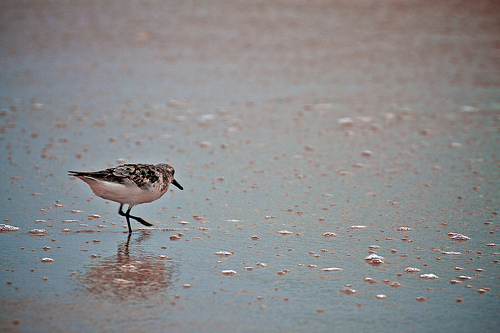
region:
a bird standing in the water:
[66, 146, 195, 229]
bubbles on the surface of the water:
[247, 204, 465, 313]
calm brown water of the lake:
[245, 30, 456, 97]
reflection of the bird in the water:
[84, 245, 179, 305]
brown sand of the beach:
[13, 288, 176, 331]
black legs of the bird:
[101, 206, 159, 239]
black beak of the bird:
[169, 177, 189, 192]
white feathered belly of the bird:
[85, 183, 166, 211]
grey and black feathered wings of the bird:
[85, 162, 165, 189]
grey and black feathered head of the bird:
[157, 158, 178, 183]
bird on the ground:
[75, 130, 207, 244]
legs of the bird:
[113, 207, 158, 245]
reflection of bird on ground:
[111, 245, 177, 305]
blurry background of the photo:
[257, 24, 337, 81]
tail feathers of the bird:
[52, 151, 102, 205]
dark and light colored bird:
[76, 149, 198, 234]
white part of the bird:
[94, 185, 154, 212]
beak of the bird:
[171, 173, 192, 197]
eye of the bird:
[167, 165, 176, 181]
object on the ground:
[206, 235, 239, 268]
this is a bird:
[67, 160, 199, 227]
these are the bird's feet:
[110, 202, 160, 234]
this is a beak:
[168, 177, 185, 194]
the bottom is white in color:
[103, 184, 120, 199]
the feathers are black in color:
[123, 168, 150, 180]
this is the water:
[72, 234, 167, 309]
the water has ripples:
[90, 248, 155, 299]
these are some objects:
[241, 174, 443, 304]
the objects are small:
[258, 188, 413, 294]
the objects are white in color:
[342, 246, 424, 271]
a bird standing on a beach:
[78, 155, 190, 234]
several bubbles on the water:
[284, 200, 484, 310]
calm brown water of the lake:
[164, 0, 464, 97]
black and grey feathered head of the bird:
[159, 160, 175, 182]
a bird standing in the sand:
[73, 151, 186, 234]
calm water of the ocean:
[133, 3, 418, 97]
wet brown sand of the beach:
[24, 273, 158, 330]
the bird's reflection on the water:
[68, 227, 177, 309]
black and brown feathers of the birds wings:
[77, 163, 167, 183]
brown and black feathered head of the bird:
[161, 155, 188, 196]